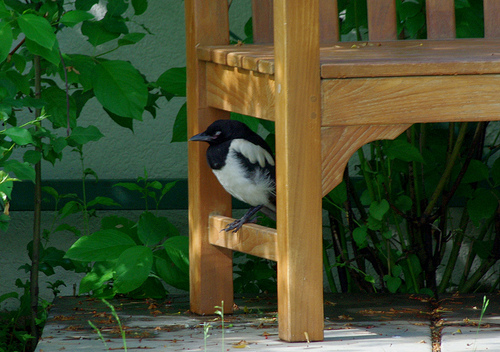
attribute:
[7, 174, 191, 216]
stripe — green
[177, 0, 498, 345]
bench — wooden, brown, light colored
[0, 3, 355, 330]
wall — white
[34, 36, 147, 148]
leaves — green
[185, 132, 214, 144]
beak — short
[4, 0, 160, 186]
leaves — bright green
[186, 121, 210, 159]
beak — black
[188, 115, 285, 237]
bird — black, white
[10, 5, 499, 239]
building — light green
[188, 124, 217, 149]
beak — black